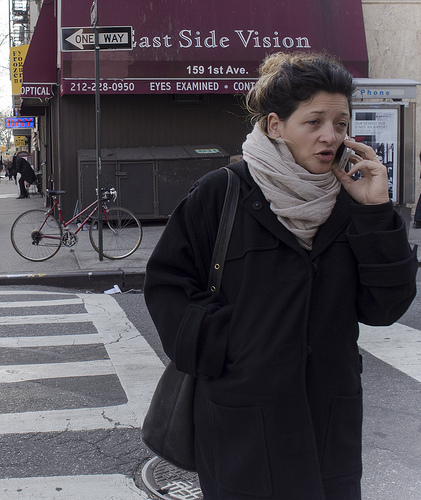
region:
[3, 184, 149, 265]
red bike leaned on pole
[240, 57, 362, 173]
woman talking on cell phone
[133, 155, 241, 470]
woman's purse on her arm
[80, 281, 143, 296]
trash on the street curb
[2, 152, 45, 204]
man sitting on bench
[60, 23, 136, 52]
one way street sign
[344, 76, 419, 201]
phone booth for pay phone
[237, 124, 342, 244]
tan scarf around woman's neck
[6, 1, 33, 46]
stairs leading to top of building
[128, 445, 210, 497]
manhole cover in road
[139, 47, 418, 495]
A WOMAN TALKING ON A CELL PHONE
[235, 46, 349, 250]
A WHITE SCARF AROUND A WOMAN'S NECK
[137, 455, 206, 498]
A METAL MANHOLE COVER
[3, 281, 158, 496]
WHITE MARKINGS ON THE PAVEMENT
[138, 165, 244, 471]
A BLACK HANDBAG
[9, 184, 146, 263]
A RED BIKE CHAINED TO A POLE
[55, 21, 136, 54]
A ONE WAY SIGN POINTING LEFT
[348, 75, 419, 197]
A PHONE BOOTH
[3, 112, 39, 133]
A RED AND BLUE SIGN THAT SAYS DAY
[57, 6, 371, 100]
A MAROON AWNING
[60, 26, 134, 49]
A black and white one way sign.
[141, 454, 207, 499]
A round manhole on the road.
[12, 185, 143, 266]
A red framed bicycle.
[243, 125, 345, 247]
A beige thick scarf.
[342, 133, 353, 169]
A silver cellphone.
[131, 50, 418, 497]
A woman on a cellphone crossing the road.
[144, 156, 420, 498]
A large black coat.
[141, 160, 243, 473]
A dark colored shoulder bag.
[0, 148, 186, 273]
The sidewalk.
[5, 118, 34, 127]
A blue and red sign.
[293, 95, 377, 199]
the woman is talking on a cellphone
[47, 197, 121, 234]
the bike is red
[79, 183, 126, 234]
the bike is hooked to the pole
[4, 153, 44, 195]
the person is sitting down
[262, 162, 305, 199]
the scarf is cream tan color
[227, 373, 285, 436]
the coat is black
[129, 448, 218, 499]
the man hole cover is in the middle of the road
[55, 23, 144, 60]
the sign is black and white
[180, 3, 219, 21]
the roof is marroon in color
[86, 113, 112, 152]
the pole is gray in color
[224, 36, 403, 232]
Woman on cell phone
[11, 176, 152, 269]
Bike parked next to sign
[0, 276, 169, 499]
Pedestrian crosswalk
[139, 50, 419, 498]
Woman talking on cell phone and carrying a purse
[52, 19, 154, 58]
One way road sign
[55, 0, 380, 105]
Eye doctors store canopy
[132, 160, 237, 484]
Black purse next to a black jacket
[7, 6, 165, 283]
Bike locked to a one way road sign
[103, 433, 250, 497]
Sewer lid in the middle of a cross walk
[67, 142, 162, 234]
Garbage bin on the side of a building